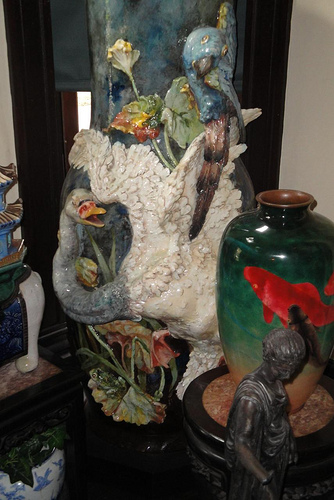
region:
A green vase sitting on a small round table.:
[179, 186, 333, 498]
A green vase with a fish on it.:
[215, 181, 333, 412]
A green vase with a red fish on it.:
[217, 184, 332, 413]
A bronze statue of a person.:
[222, 326, 308, 498]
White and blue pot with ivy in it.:
[0, 423, 66, 498]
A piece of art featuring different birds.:
[49, 0, 255, 451]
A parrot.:
[177, 3, 248, 240]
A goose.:
[52, 128, 243, 399]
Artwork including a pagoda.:
[0, 157, 44, 373]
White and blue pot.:
[0, 448, 65, 499]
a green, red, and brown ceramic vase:
[208, 178, 332, 418]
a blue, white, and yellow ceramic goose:
[49, 117, 251, 416]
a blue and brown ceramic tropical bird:
[163, 5, 277, 235]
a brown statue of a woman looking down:
[223, 320, 316, 498]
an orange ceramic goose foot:
[141, 325, 184, 374]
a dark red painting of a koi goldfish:
[241, 263, 333, 331]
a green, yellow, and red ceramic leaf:
[95, 77, 172, 145]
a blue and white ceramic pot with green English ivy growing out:
[0, 423, 81, 498]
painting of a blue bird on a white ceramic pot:
[30, 465, 52, 496]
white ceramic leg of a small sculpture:
[5, 269, 58, 377]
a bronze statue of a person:
[236, 327, 313, 484]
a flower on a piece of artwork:
[101, 37, 152, 92]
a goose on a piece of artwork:
[54, 143, 181, 314]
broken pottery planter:
[0, 461, 46, 491]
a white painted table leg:
[19, 276, 49, 373]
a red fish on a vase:
[239, 253, 330, 324]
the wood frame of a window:
[50, 91, 80, 129]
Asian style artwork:
[0, 157, 17, 258]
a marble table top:
[211, 374, 230, 422]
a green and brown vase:
[221, 191, 327, 384]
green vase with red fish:
[212, 188, 332, 413]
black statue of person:
[223, 325, 310, 498]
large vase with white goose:
[48, 0, 262, 427]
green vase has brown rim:
[215, 185, 332, 409]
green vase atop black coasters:
[181, 363, 332, 470]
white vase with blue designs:
[0, 447, 68, 497]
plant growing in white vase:
[0, 426, 62, 479]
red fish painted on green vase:
[242, 264, 333, 329]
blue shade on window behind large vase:
[49, 0, 254, 89]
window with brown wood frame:
[2, 0, 295, 266]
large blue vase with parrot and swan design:
[44, 0, 276, 463]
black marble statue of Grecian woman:
[220, 323, 324, 490]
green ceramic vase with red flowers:
[215, 187, 333, 412]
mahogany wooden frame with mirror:
[3, 1, 315, 360]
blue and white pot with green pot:
[2, 422, 76, 495]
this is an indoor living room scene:
[0, 0, 331, 490]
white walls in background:
[2, 0, 331, 288]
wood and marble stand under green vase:
[175, 358, 332, 498]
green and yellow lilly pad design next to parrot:
[100, 34, 207, 183]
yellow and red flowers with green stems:
[81, 225, 178, 428]